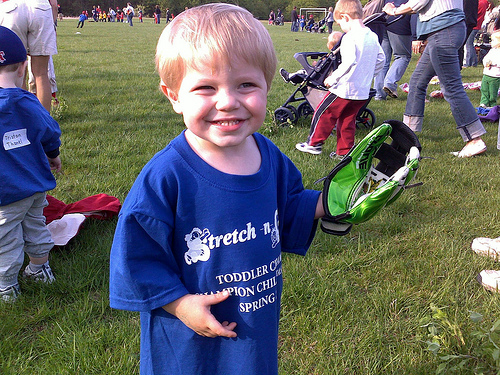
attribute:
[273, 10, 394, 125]
stroller — black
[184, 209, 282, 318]
lettering — white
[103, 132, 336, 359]
shirt — blue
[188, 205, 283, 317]
letters — white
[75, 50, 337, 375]
boy — young, smiling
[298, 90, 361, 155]
jogging pants — small, red